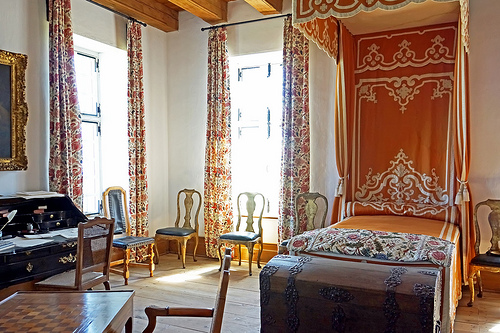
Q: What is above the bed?
A: An orange and white canopy.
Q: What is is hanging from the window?
A: Drapes.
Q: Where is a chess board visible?
A: Table in lower left corner.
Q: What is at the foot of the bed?
A: Chest.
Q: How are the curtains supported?
A: Rods.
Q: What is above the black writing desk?
A: Picture.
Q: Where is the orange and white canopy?
A: Above the bed.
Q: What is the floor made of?
A: Wood.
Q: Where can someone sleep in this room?
A: Bed.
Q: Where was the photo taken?
A: Bedroom.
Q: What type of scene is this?
A: Indoor.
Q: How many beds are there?
A: One.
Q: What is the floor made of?
A: Wood.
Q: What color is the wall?
A: White.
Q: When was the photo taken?
A: Daytime.